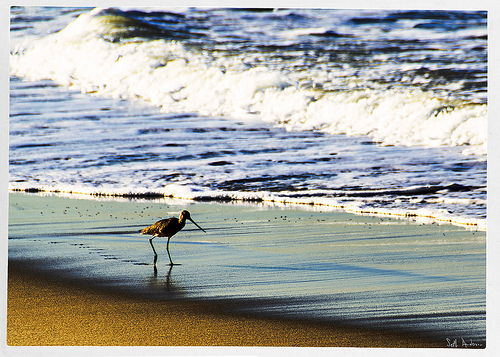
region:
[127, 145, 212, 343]
a bird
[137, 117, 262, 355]
a bird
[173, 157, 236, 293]
a bird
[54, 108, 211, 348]
a bird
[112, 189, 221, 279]
Bird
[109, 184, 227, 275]
The bird is walking on the beach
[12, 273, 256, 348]
Brown sand along the shoreline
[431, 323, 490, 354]
Signature in the right corner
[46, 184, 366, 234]
Small pebbles scattered on the ground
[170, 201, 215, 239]
Bird has a long beak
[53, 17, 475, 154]
Wave is white where it is breaking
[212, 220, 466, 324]
Ground is slightly wet from previous waves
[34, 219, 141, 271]
Bird left footprints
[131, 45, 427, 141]
Wave is about to crash on the bird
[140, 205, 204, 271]
this is a bird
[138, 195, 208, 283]
the bird is on the beach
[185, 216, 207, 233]
this is the beak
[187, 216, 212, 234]
the beak is long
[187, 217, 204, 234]
the beak is thin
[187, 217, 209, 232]
the beak is sharp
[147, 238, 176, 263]
the legs are thin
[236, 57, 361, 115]
this is the wave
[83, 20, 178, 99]
the wave is heavy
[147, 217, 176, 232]
the feathers are folded